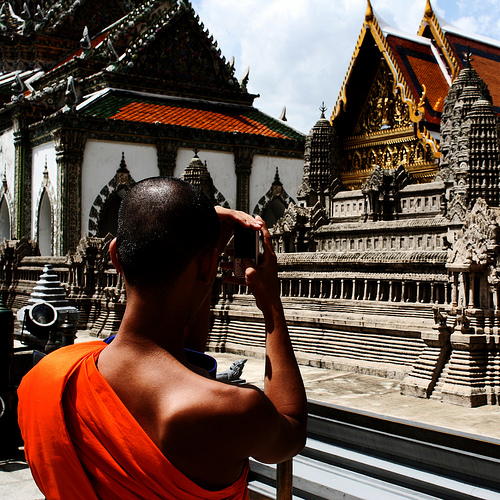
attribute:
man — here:
[16, 178, 325, 497]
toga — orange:
[10, 334, 199, 492]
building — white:
[37, 125, 310, 263]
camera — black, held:
[205, 198, 296, 274]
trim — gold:
[370, 26, 466, 138]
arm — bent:
[250, 257, 322, 447]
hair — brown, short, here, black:
[98, 156, 188, 288]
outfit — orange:
[13, 334, 222, 499]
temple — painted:
[306, 15, 499, 365]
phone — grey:
[235, 220, 254, 275]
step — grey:
[258, 302, 473, 414]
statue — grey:
[425, 119, 495, 385]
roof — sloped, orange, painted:
[344, 0, 500, 135]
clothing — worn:
[16, 329, 301, 497]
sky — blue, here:
[232, 9, 352, 122]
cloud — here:
[236, 16, 315, 165]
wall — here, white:
[170, 141, 280, 200]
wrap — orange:
[12, 320, 253, 498]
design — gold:
[360, 82, 415, 156]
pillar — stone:
[451, 61, 499, 221]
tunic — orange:
[13, 320, 203, 492]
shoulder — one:
[18, 335, 105, 431]